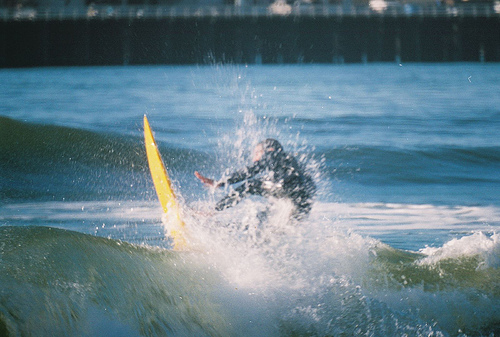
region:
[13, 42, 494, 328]
A person is in the ocean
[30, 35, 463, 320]
A person is doing a water sport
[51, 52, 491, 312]
A person is on a surfboard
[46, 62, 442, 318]
A person is having great fun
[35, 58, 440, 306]
A person is getting very wet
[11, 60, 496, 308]
A person is out in the daytime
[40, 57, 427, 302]
The person is on their day off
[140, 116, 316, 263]
surfer on a surfboard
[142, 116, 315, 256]
surfer catching a wave on surfboard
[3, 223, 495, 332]
top of a large wave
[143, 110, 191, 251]
yellow surfboard in the water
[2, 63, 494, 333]
the water is blue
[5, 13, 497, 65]
a large bridge across the water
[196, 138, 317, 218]
surfer in a black wetsuit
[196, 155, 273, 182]
the surfer's left arm extended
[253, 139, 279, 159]
the surfer's head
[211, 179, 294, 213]
the surfer's left leg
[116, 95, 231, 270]
a yellow surf board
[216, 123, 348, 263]
person in a wetsuit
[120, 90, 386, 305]
a person riding a surf board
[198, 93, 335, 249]
water splashing over the surfer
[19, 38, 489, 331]
the body of water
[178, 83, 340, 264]
a surfer with his hand out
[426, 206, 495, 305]
white caps of the wave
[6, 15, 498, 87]
a black wall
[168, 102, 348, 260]
a surfer in a crouched position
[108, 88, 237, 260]
top of surf board pointing toward the sky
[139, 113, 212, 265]
Yellow surfboard jutting out of the water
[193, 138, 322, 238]
The surfer is falling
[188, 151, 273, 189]
Arm out trying to regain balance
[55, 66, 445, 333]
Water splashing everywhere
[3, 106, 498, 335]
Sufer trying to ride good size waves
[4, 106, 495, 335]
Series of waves rolling in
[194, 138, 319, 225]
Surfer wearing a full wetsuit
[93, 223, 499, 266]
White foam from breaking wave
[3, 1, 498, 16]
People watching in the background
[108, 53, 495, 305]
Bright sun shining on the surfer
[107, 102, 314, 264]
surfer on yellow board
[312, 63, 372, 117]
ripples in blue colored water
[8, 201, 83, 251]
ripples in blue colored water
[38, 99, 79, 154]
ripples in blue colored water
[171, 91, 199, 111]
ripples in blue colored water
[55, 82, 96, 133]
ripples in blue colored water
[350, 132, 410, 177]
ripples in blue colored water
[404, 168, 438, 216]
ripples in blue colored water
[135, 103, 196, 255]
The surfboard is yellow.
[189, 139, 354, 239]
A person in the water.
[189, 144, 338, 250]
a person is surfboarding.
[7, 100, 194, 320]
The wave is big.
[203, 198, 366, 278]
The water is splashing.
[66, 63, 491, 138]
The water is blue.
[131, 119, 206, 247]
The surfboard is turned up.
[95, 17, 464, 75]
The side wall by the water.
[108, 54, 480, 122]
The water is dark and rough